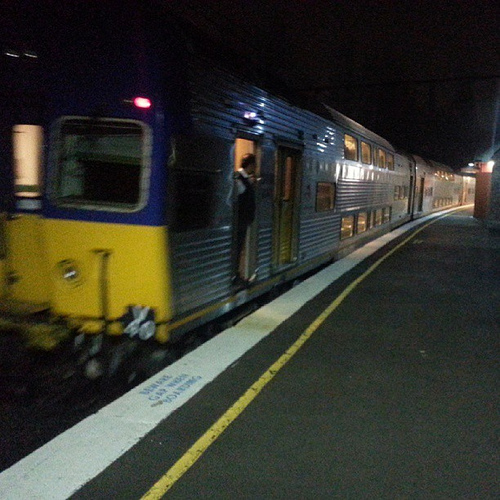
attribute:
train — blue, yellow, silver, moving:
[7, 93, 478, 331]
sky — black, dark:
[349, 1, 498, 64]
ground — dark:
[338, 359, 416, 422]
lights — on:
[462, 158, 498, 183]